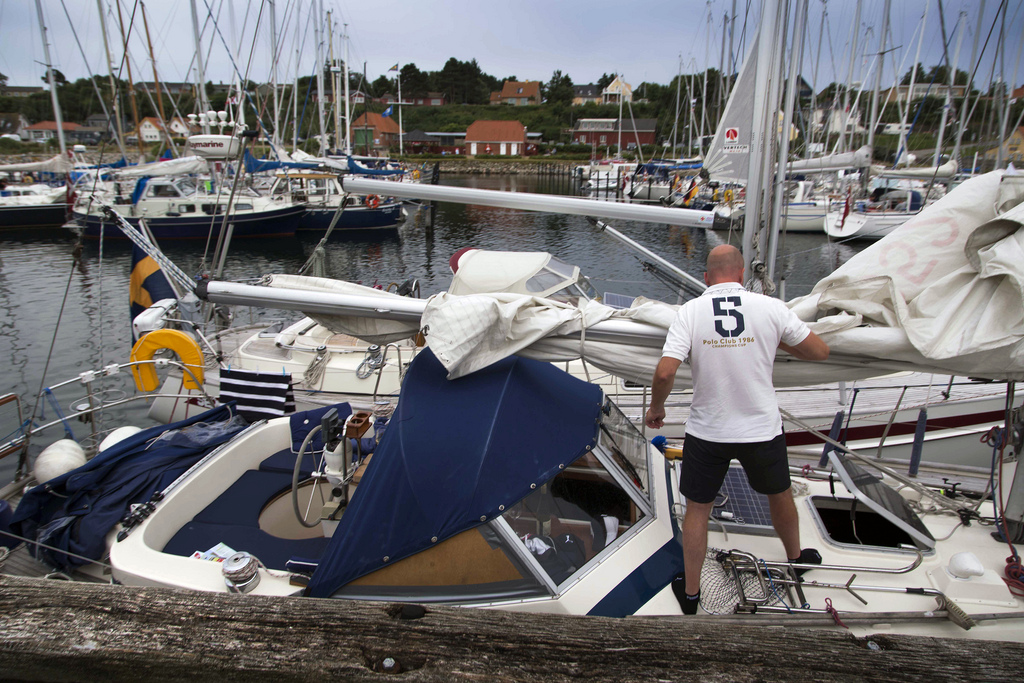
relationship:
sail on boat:
[773, 157, 1023, 379] [2, 157, 1023, 680]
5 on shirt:
[706, 285, 752, 339] [669, 285, 803, 450]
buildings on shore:
[15, 60, 1022, 182] [15, 60, 1022, 182]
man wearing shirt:
[654, 92, 842, 450] [654, 297, 842, 450]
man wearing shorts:
[643, 243, 832, 618] [644, 402, 847, 542]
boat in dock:
[110, 143, 303, 286] [110, 143, 531, 576]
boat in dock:
[145, 336, 553, 590] [145, 336, 1018, 659]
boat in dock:
[289, 173, 413, 241] [1, 6, 1023, 680]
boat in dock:
[800, 170, 931, 254] [4, 126, 1014, 678]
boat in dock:
[766, 167, 852, 232] [4, 126, 1014, 678]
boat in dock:
[618, 160, 698, 199] [4, 126, 1014, 678]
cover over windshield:
[304, 335, 600, 577] [362, 417, 656, 604]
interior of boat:
[26, 392, 362, 585] [19, 358, 1019, 631]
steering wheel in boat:
[292, 410, 356, 531] [19, 358, 1019, 631]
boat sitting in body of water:
[60, 174, 309, 250] [4, 160, 897, 475]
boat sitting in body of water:
[217, 172, 408, 231] [4, 160, 897, 475]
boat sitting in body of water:
[5, 168, 75, 229] [7, 161, 875, 510]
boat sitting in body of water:
[822, 196, 926, 239] [7, 161, 875, 510]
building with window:
[459, 114, 539, 159] [507, 132, 528, 158]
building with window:
[459, 114, 539, 159] [494, 138, 511, 167]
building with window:
[459, 114, 539, 159] [466, 133, 480, 159]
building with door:
[352, 110, 411, 156] [352, 127, 375, 156]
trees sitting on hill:
[440, 59, 483, 105] [2, 56, 1023, 146]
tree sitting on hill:
[399, 57, 431, 99] [1, 56, 1023, 161]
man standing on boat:
[643, 243, 832, 618] [0, 355, 1024, 683]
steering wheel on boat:
[290, 424, 340, 529] [19, 358, 1019, 631]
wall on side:
[10, 555, 1016, 680] [137, 575, 1010, 679]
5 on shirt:
[711, 295, 745, 338] [639, 285, 813, 453]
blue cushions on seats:
[161, 426, 340, 573] [153, 422, 337, 577]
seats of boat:
[153, 422, 337, 577] [19, 358, 1019, 631]